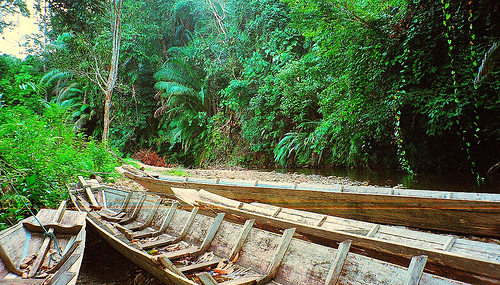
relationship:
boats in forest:
[71, 163, 493, 279] [0, 0, 497, 224]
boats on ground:
[71, 163, 493, 279] [85, 242, 135, 284]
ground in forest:
[85, 242, 135, 284] [0, 0, 497, 224]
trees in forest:
[60, 4, 480, 124] [0, 0, 497, 224]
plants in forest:
[18, 102, 122, 186] [0, 0, 497, 224]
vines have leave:
[390, 49, 496, 138] [453, 91, 459, 94]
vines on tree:
[390, 49, 496, 138] [379, 0, 496, 176]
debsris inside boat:
[20, 252, 57, 279] [11, 207, 87, 281]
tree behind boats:
[379, 0, 496, 176] [71, 163, 493, 279]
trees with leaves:
[60, 0, 165, 151] [89, 14, 143, 128]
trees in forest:
[60, 0, 165, 151] [0, 0, 497, 224]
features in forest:
[53, 14, 456, 151] [0, 0, 497, 224]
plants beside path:
[18, 102, 122, 186] [120, 126, 170, 175]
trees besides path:
[60, 4, 480, 124] [120, 126, 170, 175]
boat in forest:
[11, 207, 87, 281] [0, 0, 497, 224]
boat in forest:
[172, 178, 390, 239] [0, 0, 497, 224]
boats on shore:
[71, 163, 493, 279] [207, 158, 324, 184]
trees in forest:
[60, 4, 480, 124] [23, 12, 496, 159]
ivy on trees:
[389, 87, 411, 183] [60, 4, 480, 124]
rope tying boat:
[7, 177, 60, 242] [11, 207, 87, 281]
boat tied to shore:
[11, 207, 87, 281] [207, 158, 324, 184]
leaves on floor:
[89, 14, 143, 128] [192, 219, 278, 281]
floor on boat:
[192, 219, 278, 281] [172, 178, 390, 239]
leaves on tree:
[89, 14, 143, 128] [379, 0, 496, 176]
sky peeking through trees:
[5, 1, 55, 50] [60, 4, 480, 124]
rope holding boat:
[7, 177, 60, 242] [11, 207, 87, 281]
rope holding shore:
[7, 177, 60, 242] [207, 158, 324, 184]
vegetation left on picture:
[15, 136, 122, 191] [11, 9, 500, 262]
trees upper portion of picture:
[60, 4, 480, 124] [11, 9, 500, 262]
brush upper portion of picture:
[188, 39, 433, 133] [11, 9, 500, 262]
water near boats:
[335, 161, 495, 197] [71, 163, 493, 279]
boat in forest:
[0, 205, 89, 285] [23, 12, 496, 159]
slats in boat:
[156, 203, 179, 230] [172, 178, 390, 239]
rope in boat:
[7, 177, 60, 242] [11, 207, 87, 281]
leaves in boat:
[191, 256, 231, 283] [11, 207, 87, 281]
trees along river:
[60, 4, 480, 124] [301, 157, 482, 200]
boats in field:
[71, 163, 493, 279] [51, 141, 496, 269]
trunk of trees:
[95, 99, 120, 145] [60, 0, 165, 151]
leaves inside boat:
[191, 256, 231, 283] [172, 178, 390, 239]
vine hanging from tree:
[382, 76, 479, 172] [379, 11, 496, 172]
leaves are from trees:
[89, 14, 143, 128] [60, 0, 165, 151]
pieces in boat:
[102, 206, 143, 245] [90, 179, 192, 263]